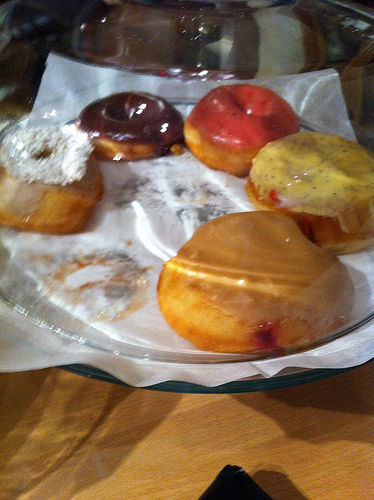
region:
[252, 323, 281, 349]
jelly filling coming out of a hole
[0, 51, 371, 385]
a white paper under donuts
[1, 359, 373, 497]
a light brown wood table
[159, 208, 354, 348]
a jelly filled donut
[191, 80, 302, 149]
pink icing on a donut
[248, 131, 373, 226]
yellow icing on a donut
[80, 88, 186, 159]
chocolate icing on a donut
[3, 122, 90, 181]
powdered sugar on top of a donut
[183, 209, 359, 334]
caramel icing on top of a donut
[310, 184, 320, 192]
a dark speck in yellow icing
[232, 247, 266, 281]
the frosting is tan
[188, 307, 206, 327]
the donut is golden brown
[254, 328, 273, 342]
the jelly is red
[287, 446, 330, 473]
the table is brown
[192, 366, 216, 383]
the paper is white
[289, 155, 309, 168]
the frosting is yellow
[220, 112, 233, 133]
the frosting is pink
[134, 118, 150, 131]
the frosting is dark brown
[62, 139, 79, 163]
the topping is white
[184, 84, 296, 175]
A pink frosted donut.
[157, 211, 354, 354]
A jelly filled donut.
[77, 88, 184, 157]
A chocolate frosted donut.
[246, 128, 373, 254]
A yellow frosted donut.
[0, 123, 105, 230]
A donut with white on it.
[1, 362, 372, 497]
Light wood table top.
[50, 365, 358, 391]
A large serving plate.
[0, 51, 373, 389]
White food wrapper paper.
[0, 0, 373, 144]
A very blurry background.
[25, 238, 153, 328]
A brown food stain.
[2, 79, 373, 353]
five donuts under a glass dome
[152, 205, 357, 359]
round donut with jam escaping from a hole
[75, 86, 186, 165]
chocolate frosted ring donut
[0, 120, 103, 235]
ring donut with coconut on top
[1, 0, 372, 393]
glass dome sits on a plate full of donuts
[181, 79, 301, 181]
pink frosted donut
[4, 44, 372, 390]
parchment paper under some donuts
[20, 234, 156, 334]
a dirty mark left by a donut that was taken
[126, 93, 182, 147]
lights reflected in chocolate frosting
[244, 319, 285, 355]
raspberry jam escaping from a donut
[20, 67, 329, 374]
a large plate of doughnuts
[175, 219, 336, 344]
a doughnut filled with jelly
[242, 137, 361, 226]
a doughnut with yellow icing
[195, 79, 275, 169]
a doughnut with pink icing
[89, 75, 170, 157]
a doughnut with chocolate icing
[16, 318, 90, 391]
a piece of wax paper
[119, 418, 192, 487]
a light brown tabletop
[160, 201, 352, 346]
A piece of food.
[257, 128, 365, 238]
A piece of food.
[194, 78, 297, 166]
A piece of food.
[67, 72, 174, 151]
A piece of food.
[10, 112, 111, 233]
A piece of food.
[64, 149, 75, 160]
A piece of food.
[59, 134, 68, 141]
A piece of food.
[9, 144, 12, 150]
A piece of food.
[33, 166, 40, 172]
A piece of food.